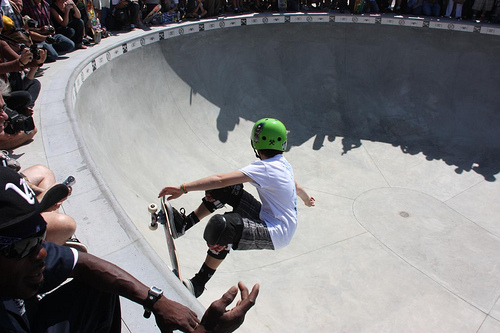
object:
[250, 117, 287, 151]
plastic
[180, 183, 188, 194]
bracelets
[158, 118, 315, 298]
boy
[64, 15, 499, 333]
skate bowl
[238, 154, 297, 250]
t-shirt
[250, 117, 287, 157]
helmet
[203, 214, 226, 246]
pads